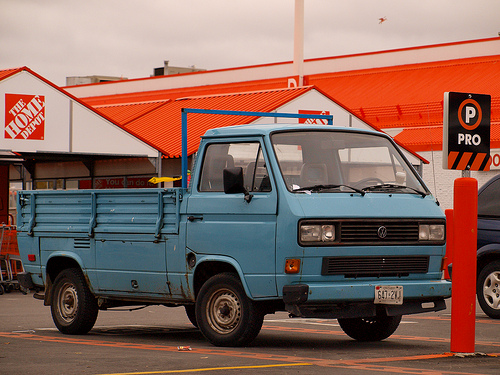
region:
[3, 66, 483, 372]
a blue truck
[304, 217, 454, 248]
headlights on the truck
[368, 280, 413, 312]
the license plate of the truck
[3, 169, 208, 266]
the bed of the blue truck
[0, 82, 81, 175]
an orange logo on the building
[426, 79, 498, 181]
a black parking sign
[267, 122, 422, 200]
the windshield of the truck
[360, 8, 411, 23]
a flying object in the sky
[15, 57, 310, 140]
an orange roof of the building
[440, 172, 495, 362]
an orange pole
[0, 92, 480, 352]
Blue Volkswagon truck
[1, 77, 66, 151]
The Home Depot sign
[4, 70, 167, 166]
The sign is orange and white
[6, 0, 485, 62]
The sky is grey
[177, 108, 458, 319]
Cab of the truck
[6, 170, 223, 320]
Bed of the truck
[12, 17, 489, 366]
No people shown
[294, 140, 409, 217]
Left hand driver's side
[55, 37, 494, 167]
The building roof is orange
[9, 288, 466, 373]
Orange lines on the asphalt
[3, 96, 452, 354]
a blue truck in front a home depot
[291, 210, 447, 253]
two headlights in front a truck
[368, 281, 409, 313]
a white plate on bumper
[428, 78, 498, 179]
a sign on an orange pole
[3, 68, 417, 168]
a building of "The Home Depot"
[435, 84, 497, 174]
sign has a P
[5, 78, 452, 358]
truck is old model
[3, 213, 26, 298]
shopping cart in front of store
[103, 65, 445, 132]
an orange roof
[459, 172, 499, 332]
part of a black car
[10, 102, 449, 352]
a blue pickup truck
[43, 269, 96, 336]
a right rear truck tire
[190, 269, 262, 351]
a right front truck tire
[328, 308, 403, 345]
a left front truck tire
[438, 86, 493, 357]
a red and black parking sign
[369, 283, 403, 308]
a white license plate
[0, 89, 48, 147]
The Home Depot corporate logo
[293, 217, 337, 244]
a right front headlight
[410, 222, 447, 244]
a right front headlight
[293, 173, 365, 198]
a passenger side windshield wiper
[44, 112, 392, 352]
blue truck in photo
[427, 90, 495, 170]
black and orange sign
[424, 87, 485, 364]
orange pole with black sign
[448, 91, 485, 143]
white p in orange circle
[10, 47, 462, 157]
orange and white building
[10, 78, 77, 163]
orange sign says the home depot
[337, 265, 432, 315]
white license plate in photo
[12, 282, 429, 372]
orange lines on pavement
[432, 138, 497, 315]
blue van in photo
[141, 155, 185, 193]
something yellow on truck